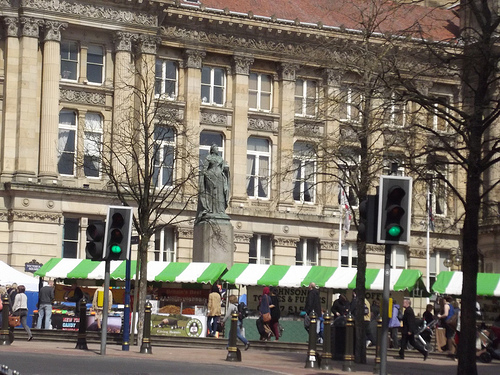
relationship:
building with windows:
[3, 6, 484, 335] [55, 42, 449, 303]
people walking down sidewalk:
[249, 284, 286, 332] [200, 335, 306, 365]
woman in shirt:
[7, 284, 28, 297] [12, 290, 32, 306]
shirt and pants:
[12, 290, 32, 306] [13, 300, 28, 319]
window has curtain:
[56, 95, 112, 183] [83, 107, 107, 166]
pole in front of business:
[218, 278, 234, 351] [208, 261, 362, 343]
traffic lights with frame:
[383, 178, 412, 242] [363, 158, 423, 253]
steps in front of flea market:
[18, 336, 368, 365] [33, 248, 468, 371]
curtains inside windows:
[243, 134, 273, 191] [230, 118, 295, 213]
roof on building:
[248, 6, 474, 46] [138, 16, 456, 297]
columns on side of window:
[34, 27, 60, 182] [64, 98, 104, 183]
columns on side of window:
[111, 38, 142, 172] [64, 98, 104, 183]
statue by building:
[191, 140, 232, 220] [3, 6, 484, 335]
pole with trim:
[221, 310, 245, 363] [230, 310, 240, 320]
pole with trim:
[221, 310, 245, 363] [223, 341, 241, 352]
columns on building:
[41, 27, 60, 182] [3, 6, 484, 335]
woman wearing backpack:
[217, 290, 252, 350] [237, 297, 248, 321]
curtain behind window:
[86, 119, 98, 173] [80, 107, 110, 179]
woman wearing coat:
[385, 301, 413, 352] [384, 305, 405, 331]